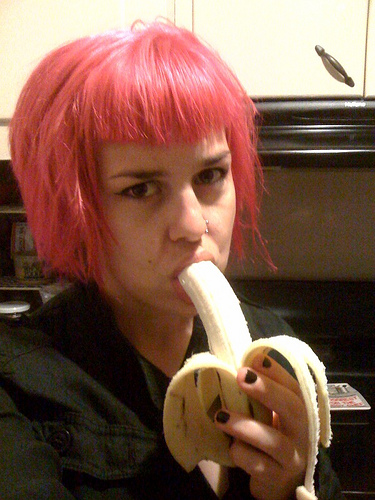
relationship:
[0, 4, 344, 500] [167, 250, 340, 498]
girl eating banana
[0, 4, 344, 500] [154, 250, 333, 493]
girl eating banana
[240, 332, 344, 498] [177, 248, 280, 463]
peelings on banana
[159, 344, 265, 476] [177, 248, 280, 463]
peelings on banana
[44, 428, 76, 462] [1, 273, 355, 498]
button on shirt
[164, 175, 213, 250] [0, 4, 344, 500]
nose on girl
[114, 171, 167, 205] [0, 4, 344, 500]
eyes on girl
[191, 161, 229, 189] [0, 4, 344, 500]
eyes on girl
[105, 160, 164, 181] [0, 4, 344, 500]
eyebrow on girl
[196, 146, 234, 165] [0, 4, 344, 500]
eyebrow on girl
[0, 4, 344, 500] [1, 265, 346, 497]
girl wearing top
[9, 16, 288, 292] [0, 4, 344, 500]
hair on girl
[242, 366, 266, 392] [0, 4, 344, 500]
nail on girl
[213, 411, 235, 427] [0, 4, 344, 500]
nail on girl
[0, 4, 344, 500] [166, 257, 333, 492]
girl holding fruit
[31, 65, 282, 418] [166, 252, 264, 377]
girl with banana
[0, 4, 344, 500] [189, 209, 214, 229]
girl with piercing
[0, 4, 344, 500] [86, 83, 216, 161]
girl with bangs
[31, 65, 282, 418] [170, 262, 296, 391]
girl with banana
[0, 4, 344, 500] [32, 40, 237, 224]
girl with hair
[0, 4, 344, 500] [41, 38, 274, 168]
girl with hair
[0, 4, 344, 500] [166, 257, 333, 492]
girl eating fruit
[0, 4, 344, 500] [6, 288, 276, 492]
girl wearing shirt